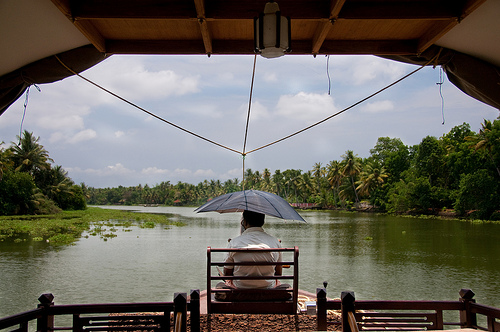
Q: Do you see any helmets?
A: No, there are no helmets.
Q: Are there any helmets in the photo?
A: No, there are no helmets.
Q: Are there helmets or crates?
A: No, there are no helmets or crates.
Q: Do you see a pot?
A: No, there are no pots.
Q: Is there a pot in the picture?
A: No, there are no pots.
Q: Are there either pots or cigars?
A: No, there are no pots or cigars.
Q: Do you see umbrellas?
A: Yes, there is an umbrella.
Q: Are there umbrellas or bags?
A: Yes, there is an umbrella.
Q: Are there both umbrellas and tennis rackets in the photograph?
A: No, there is an umbrella but no rackets.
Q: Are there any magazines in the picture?
A: No, there are no magazines.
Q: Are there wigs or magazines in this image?
A: No, there are no magazines or wigs.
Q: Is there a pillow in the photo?
A: No, there are no pillows.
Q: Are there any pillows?
A: No, there are no pillows.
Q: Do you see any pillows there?
A: No, there are no pillows.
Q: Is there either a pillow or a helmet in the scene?
A: No, there are no pillows or helmets.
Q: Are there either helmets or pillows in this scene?
A: No, there are no pillows or helmets.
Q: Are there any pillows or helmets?
A: No, there are no pillows or helmets.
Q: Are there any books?
A: No, there are no books.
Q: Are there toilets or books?
A: No, there are no books or toilets.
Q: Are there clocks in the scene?
A: No, there are no clocks.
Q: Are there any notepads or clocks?
A: No, there are no clocks or notepads.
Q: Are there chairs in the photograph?
A: Yes, there is a chair.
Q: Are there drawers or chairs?
A: Yes, there is a chair.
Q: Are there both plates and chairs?
A: No, there is a chair but no plates.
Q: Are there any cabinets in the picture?
A: No, there are no cabinets.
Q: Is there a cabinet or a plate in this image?
A: No, there are no cabinets or plates.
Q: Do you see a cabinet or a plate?
A: No, there are no cabinets or plates.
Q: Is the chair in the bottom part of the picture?
A: Yes, the chair is in the bottom of the image.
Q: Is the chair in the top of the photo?
A: No, the chair is in the bottom of the image.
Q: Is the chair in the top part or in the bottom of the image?
A: The chair is in the bottom of the image.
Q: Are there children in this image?
A: No, there are no children.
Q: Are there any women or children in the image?
A: No, there are no children or women.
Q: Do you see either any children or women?
A: No, there are no children or women.